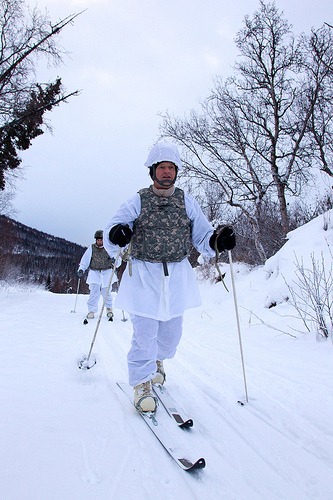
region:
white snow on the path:
[34, 305, 53, 340]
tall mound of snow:
[264, 217, 332, 294]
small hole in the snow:
[257, 293, 294, 316]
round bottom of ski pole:
[75, 350, 101, 372]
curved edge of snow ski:
[179, 458, 215, 473]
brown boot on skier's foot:
[128, 370, 165, 411]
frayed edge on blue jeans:
[124, 342, 196, 386]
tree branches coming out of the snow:
[276, 255, 319, 329]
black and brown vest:
[131, 180, 198, 266]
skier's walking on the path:
[80, 144, 248, 379]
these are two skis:
[106, 389, 203, 459]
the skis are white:
[154, 378, 191, 462]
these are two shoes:
[112, 362, 191, 385]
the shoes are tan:
[127, 370, 191, 490]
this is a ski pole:
[81, 332, 104, 334]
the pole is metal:
[81, 331, 109, 347]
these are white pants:
[137, 346, 235, 418]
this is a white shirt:
[126, 301, 146, 310]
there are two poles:
[53, 298, 322, 411]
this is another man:
[52, 284, 140, 331]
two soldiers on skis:
[67, 129, 265, 470]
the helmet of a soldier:
[144, 139, 184, 163]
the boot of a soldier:
[133, 377, 156, 411]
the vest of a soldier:
[133, 184, 197, 266]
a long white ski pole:
[226, 249, 265, 414]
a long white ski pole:
[78, 249, 117, 376]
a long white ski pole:
[70, 273, 81, 317]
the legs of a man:
[127, 308, 184, 414]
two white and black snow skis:
[116, 369, 207, 478]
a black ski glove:
[209, 223, 239, 257]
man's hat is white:
[129, 132, 188, 199]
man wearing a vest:
[130, 185, 197, 263]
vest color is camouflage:
[131, 189, 193, 270]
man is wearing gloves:
[97, 219, 235, 265]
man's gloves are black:
[96, 214, 236, 265]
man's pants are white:
[115, 302, 188, 389]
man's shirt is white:
[95, 187, 227, 263]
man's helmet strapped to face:
[142, 143, 186, 194]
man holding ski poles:
[67, 210, 258, 405]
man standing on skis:
[109, 362, 221, 487]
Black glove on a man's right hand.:
[111, 222, 133, 248]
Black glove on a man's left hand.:
[210, 226, 236, 253]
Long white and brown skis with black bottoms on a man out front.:
[116, 370, 208, 471]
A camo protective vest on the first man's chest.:
[126, 185, 194, 263]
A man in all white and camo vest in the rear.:
[76, 231, 124, 319]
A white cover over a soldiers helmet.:
[144, 142, 183, 168]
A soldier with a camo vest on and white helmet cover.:
[101, 142, 236, 410]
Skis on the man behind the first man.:
[82, 309, 114, 325]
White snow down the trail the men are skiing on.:
[5, 282, 331, 498]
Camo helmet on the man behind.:
[93, 229, 103, 239]